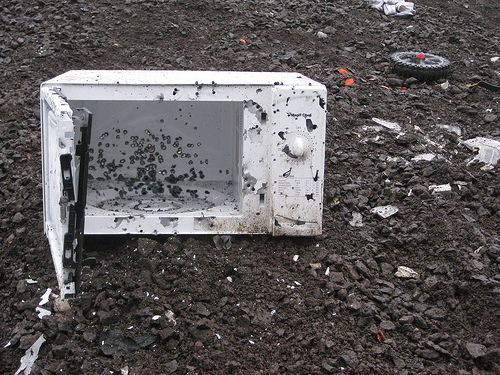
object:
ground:
[194, 260, 461, 350]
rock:
[393, 265, 417, 281]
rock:
[379, 318, 397, 330]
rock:
[424, 307, 445, 318]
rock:
[426, 331, 450, 340]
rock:
[354, 258, 371, 274]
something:
[397, 85, 408, 92]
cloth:
[371, 0, 417, 17]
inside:
[66, 103, 241, 210]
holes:
[137, 165, 158, 175]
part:
[75, 107, 95, 271]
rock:
[357, 112, 424, 144]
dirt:
[271, 250, 491, 364]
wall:
[102, 102, 230, 189]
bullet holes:
[86, 107, 210, 196]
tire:
[388, 31, 469, 93]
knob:
[284, 134, 309, 159]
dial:
[78, 122, 241, 215]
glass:
[98, 180, 222, 215]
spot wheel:
[404, 49, 433, 69]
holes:
[144, 132, 160, 143]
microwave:
[39, 68, 327, 299]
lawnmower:
[2, 50, 359, 282]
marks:
[156, 116, 166, 123]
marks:
[175, 107, 182, 113]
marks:
[192, 126, 199, 133]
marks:
[191, 124, 199, 131]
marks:
[189, 103, 196, 108]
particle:
[143, 150, 150, 157]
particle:
[98, 130, 109, 140]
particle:
[159, 132, 171, 144]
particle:
[145, 141, 151, 150]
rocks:
[155, 287, 307, 363]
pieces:
[331, 65, 356, 87]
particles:
[328, 60, 408, 93]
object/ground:
[389, 51, 449, 81]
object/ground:
[37, 67, 326, 303]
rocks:
[341, 108, 467, 275]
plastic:
[35, 68, 330, 302]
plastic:
[464, 136, 499, 166]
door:
[39, 87, 92, 302]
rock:
[194, 300, 209, 317]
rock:
[219, 282, 234, 293]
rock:
[94, 307, 111, 319]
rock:
[137, 236, 159, 255]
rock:
[192, 337, 205, 350]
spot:
[416, 52, 425, 59]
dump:
[0, 0, 493, 375]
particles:
[345, 108, 475, 218]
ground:
[2, 0, 342, 55]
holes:
[100, 159, 120, 174]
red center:
[413, 48, 425, 62]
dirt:
[0, 300, 500, 375]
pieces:
[350, 116, 498, 166]